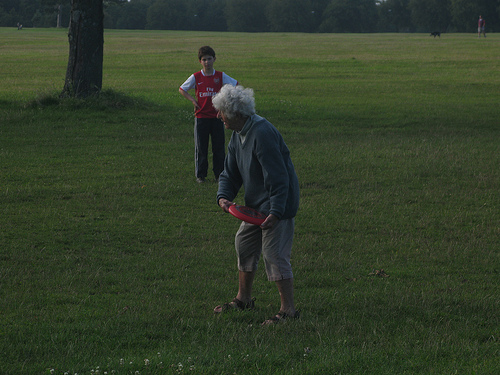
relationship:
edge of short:
[264, 269, 294, 283] [228, 213, 301, 284]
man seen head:
[203, 82, 310, 326] [207, 79, 267, 138]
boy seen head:
[172, 40, 234, 188] [187, 41, 227, 81]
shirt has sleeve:
[175, 71, 242, 122] [181, 73, 198, 92]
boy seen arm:
[172, 40, 234, 188] [173, 73, 204, 109]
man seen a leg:
[203, 82, 310, 326] [259, 220, 309, 327]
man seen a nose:
[203, 82, 310, 326] [214, 109, 223, 120]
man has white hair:
[203, 82, 310, 326] [207, 79, 267, 138]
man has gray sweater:
[203, 82, 310, 326] [210, 121, 303, 223]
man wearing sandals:
[203, 82, 310, 326] [207, 294, 302, 333]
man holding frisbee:
[203, 82, 310, 326] [223, 203, 268, 229]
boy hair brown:
[172, 40, 234, 188] [187, 41, 227, 81]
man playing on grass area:
[203, 82, 310, 326] [1, 24, 492, 374]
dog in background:
[12, 20, 26, 38] [6, 7, 499, 42]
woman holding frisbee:
[203, 82, 310, 326] [223, 203, 268, 229]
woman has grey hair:
[203, 82, 310, 326] [207, 79, 267, 138]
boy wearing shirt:
[172, 40, 234, 188] [175, 71, 242, 122]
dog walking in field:
[428, 27, 446, 38] [339, 24, 497, 97]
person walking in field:
[473, 10, 490, 37] [339, 24, 497, 97]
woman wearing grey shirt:
[203, 82, 310, 326] [210, 121, 303, 223]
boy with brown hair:
[172, 40, 234, 188] [187, 41, 227, 81]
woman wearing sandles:
[203, 82, 310, 326] [207, 294, 302, 333]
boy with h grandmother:
[172, 40, 234, 188] [203, 82, 310, 326]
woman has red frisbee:
[203, 82, 310, 326] [223, 203, 268, 229]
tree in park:
[58, 1, 111, 101] [1, 24, 492, 374]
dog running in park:
[428, 27, 446, 38] [1, 24, 492, 374]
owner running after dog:
[471, 4, 492, 43] [428, 27, 446, 38]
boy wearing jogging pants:
[172, 40, 234, 188] [191, 115, 227, 178]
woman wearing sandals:
[203, 82, 310, 326] [207, 294, 302, 333]